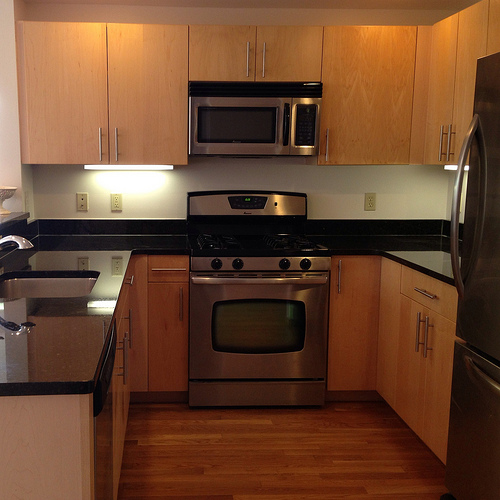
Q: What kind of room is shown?
A: It is a kitchen.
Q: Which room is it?
A: It is a kitchen.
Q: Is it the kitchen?
A: Yes, it is the kitchen.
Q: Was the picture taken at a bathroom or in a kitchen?
A: It was taken at a kitchen.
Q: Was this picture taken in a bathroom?
A: No, the picture was taken in a kitchen.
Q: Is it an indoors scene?
A: Yes, it is indoors.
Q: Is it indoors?
A: Yes, it is indoors.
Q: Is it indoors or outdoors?
A: It is indoors.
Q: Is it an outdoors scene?
A: No, it is indoors.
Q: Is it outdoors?
A: No, it is indoors.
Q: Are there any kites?
A: No, there are no kites.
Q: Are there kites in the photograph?
A: No, there are no kites.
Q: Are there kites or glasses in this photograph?
A: No, there are no kites or glasses.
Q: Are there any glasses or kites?
A: No, there are no kites or glasses.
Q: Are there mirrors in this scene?
A: No, there are no mirrors.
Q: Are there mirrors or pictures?
A: No, there are no mirrors or pictures.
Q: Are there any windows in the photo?
A: Yes, there is a window.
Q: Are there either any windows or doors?
A: Yes, there is a window.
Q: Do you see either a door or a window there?
A: Yes, there is a window.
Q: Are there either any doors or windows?
A: Yes, there is a window.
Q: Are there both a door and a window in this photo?
A: Yes, there are both a window and a door.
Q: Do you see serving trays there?
A: No, there are no serving trays.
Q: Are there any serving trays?
A: No, there are no serving trays.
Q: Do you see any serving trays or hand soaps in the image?
A: No, there are no serving trays or hand soaps.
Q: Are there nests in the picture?
A: No, there are no nests.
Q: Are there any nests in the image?
A: No, there are no nests.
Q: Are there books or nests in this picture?
A: No, there are no nests or books.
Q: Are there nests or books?
A: No, there are no nests or books.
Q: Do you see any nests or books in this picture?
A: No, there are no nests or books.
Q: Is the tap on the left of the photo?
A: Yes, the tap is on the left of the image.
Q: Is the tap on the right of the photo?
A: No, the tap is on the left of the image.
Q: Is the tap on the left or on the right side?
A: The tap is on the left of the image.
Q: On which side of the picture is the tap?
A: The tap is on the left of the image.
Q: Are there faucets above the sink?
A: Yes, there is a faucet above the sink.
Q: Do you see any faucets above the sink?
A: Yes, there is a faucet above the sink.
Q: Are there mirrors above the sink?
A: No, there is a faucet above the sink.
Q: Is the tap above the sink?
A: Yes, the tap is above the sink.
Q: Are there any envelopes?
A: No, there are no envelopes.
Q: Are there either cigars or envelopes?
A: No, there are no envelopes or cigars.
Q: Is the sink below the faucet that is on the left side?
A: Yes, the sink is below the faucet.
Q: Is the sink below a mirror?
A: No, the sink is below the faucet.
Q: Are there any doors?
A: Yes, there is a door.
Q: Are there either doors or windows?
A: Yes, there is a door.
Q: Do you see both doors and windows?
A: Yes, there are both a door and a window.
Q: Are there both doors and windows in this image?
A: Yes, there are both a door and a window.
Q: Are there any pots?
A: No, there are no pots.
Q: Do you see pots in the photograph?
A: No, there are no pots.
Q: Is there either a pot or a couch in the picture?
A: No, there are no pots or couches.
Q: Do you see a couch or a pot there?
A: No, there are no pots or couches.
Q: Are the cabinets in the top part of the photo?
A: Yes, the cabinets are in the top of the image.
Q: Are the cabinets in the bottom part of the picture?
A: No, the cabinets are in the top of the image.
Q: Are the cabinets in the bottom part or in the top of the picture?
A: The cabinets are in the top of the image.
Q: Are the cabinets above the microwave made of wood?
A: Yes, the cabinets are made of wood.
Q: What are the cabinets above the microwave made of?
A: The cabinets are made of wood.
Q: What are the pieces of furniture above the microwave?
A: The pieces of furniture are cabinets.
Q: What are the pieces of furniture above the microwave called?
A: The pieces of furniture are cabinets.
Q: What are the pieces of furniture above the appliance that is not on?
A: The pieces of furniture are cabinets.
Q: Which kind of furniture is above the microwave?
A: The pieces of furniture are cabinets.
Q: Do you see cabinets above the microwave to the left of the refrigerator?
A: Yes, there are cabinets above the microwave.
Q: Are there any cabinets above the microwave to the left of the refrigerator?
A: Yes, there are cabinets above the microwave.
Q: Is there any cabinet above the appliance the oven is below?
A: Yes, there are cabinets above the microwave.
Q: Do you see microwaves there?
A: Yes, there is a microwave.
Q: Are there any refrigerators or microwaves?
A: Yes, there is a microwave.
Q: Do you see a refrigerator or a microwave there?
A: Yes, there is a microwave.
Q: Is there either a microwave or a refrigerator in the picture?
A: Yes, there is a microwave.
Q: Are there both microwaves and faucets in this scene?
A: Yes, there are both a microwave and a faucet.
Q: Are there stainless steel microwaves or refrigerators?
A: Yes, there is a stainless steel microwave.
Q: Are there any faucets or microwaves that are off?
A: Yes, the microwave is off.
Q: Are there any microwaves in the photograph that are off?
A: Yes, there is a microwave that is off.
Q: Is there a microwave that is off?
A: Yes, there is a microwave that is off.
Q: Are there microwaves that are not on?
A: Yes, there is a microwave that is off.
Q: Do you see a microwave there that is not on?
A: Yes, there is a microwave that is off .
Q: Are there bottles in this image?
A: No, there are no bottles.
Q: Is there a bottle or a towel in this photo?
A: No, there are no bottles or towels.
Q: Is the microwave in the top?
A: Yes, the microwave is in the top of the image.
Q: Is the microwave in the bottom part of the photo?
A: No, the microwave is in the top of the image.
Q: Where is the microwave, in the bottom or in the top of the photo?
A: The microwave is in the top of the image.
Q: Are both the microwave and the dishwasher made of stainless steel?
A: Yes, both the microwave and the dishwasher are made of stainless steel.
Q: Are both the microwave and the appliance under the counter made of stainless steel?
A: Yes, both the microwave and the dishwasher are made of stainless steel.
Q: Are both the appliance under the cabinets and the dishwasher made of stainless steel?
A: Yes, both the microwave and the dishwasher are made of stainless steel.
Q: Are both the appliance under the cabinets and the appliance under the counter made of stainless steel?
A: Yes, both the microwave and the dishwasher are made of stainless steel.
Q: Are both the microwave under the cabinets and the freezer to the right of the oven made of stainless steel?
A: Yes, both the microwave and the refrigerator are made of stainless steel.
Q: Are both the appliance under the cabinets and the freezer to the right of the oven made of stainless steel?
A: Yes, both the microwave and the refrigerator are made of stainless steel.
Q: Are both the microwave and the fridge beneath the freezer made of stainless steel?
A: Yes, both the microwave and the refrigerator are made of stainless steel.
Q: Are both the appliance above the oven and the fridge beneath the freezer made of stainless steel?
A: Yes, both the microwave and the refrigerator are made of stainless steel.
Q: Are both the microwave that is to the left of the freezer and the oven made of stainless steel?
A: Yes, both the microwave and the oven are made of stainless steel.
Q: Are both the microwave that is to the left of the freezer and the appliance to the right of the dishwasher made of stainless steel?
A: Yes, both the microwave and the oven are made of stainless steel.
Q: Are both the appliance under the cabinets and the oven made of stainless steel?
A: Yes, both the microwave and the oven are made of stainless steel.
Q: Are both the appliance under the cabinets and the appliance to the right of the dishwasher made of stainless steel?
A: Yes, both the microwave and the oven are made of stainless steel.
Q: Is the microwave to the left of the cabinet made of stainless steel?
A: Yes, the microwave is made of stainless steel.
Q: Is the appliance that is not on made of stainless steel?
A: Yes, the microwave is made of stainless steel.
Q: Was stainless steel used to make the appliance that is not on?
A: Yes, the microwave is made of stainless steel.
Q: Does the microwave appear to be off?
A: Yes, the microwave is off.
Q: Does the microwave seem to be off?
A: Yes, the microwave is off.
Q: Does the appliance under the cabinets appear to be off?
A: Yes, the microwave is off.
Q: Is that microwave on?
A: No, the microwave is off.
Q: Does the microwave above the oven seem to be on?
A: No, the microwave is off.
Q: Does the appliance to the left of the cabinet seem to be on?
A: No, the microwave is off.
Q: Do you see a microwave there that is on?
A: No, there is a microwave but it is off.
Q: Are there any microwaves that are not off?
A: No, there is a microwave but it is off.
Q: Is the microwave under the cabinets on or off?
A: The microwave is off.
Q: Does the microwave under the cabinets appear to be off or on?
A: The microwave is off.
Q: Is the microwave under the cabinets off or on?
A: The microwave is off.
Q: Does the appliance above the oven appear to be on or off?
A: The microwave is off.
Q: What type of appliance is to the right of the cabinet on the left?
A: The appliance is a microwave.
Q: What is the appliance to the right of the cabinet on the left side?
A: The appliance is a microwave.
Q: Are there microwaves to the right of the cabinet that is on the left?
A: Yes, there is a microwave to the right of the cabinet.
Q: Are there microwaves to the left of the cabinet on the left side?
A: No, the microwave is to the right of the cabinet.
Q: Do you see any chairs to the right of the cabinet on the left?
A: No, there is a microwave to the right of the cabinet.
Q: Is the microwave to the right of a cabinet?
A: Yes, the microwave is to the right of a cabinet.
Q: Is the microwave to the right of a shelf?
A: No, the microwave is to the right of a cabinet.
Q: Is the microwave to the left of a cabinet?
A: No, the microwave is to the right of a cabinet.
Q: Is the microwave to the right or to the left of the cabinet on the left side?
A: The microwave is to the right of the cabinet.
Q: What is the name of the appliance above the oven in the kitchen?
A: The appliance is a microwave.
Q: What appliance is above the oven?
A: The appliance is a microwave.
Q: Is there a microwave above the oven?
A: Yes, there is a microwave above the oven.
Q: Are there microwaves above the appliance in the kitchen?
A: Yes, there is a microwave above the oven.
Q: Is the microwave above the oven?
A: Yes, the microwave is above the oven.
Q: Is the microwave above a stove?
A: No, the microwave is above the oven.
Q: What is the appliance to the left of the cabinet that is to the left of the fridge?
A: The appliance is a microwave.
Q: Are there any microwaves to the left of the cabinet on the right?
A: Yes, there is a microwave to the left of the cabinet.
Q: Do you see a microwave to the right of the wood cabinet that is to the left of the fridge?
A: No, the microwave is to the left of the cabinet.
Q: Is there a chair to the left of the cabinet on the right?
A: No, there is a microwave to the left of the cabinet.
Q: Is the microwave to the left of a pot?
A: No, the microwave is to the left of a cabinet.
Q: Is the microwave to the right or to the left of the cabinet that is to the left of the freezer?
A: The microwave is to the left of the cabinet.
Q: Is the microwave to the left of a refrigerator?
A: Yes, the microwave is to the left of a refrigerator.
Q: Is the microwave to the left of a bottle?
A: No, the microwave is to the left of a refrigerator.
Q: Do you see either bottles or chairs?
A: No, there are no chairs or bottles.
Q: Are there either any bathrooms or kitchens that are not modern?
A: No, there is a kitchen but it is modern.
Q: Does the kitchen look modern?
A: Yes, the kitchen is modern.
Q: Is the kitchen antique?
A: No, the kitchen is modern.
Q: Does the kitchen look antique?
A: No, the kitchen is modern.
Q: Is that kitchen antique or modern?
A: The kitchen is modern.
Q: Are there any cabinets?
A: Yes, there is a cabinet.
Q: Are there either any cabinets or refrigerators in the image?
A: Yes, there is a cabinet.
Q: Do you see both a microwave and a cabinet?
A: Yes, there are both a cabinet and a microwave.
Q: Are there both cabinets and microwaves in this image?
A: Yes, there are both a cabinet and a microwave.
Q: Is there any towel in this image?
A: No, there are no towels.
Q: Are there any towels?
A: No, there are no towels.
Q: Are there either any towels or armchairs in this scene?
A: No, there are no towels or armchairs.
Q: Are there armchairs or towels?
A: No, there are no towels or armchairs.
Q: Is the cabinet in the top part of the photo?
A: Yes, the cabinet is in the top of the image.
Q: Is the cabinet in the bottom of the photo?
A: No, the cabinet is in the top of the image.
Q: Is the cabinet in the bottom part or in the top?
A: The cabinet is in the top of the image.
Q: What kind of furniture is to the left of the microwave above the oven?
A: The piece of furniture is a cabinet.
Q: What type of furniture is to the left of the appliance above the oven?
A: The piece of furniture is a cabinet.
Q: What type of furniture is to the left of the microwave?
A: The piece of furniture is a cabinet.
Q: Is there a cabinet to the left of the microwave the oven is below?
A: Yes, there is a cabinet to the left of the microwave.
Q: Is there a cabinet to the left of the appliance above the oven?
A: Yes, there is a cabinet to the left of the microwave.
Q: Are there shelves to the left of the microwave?
A: No, there is a cabinet to the left of the microwave.